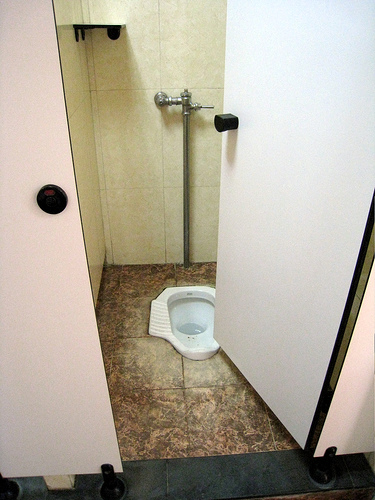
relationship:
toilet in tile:
[143, 286, 226, 356] [120, 388, 187, 457]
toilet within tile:
[143, 286, 226, 356] [120, 388, 187, 457]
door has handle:
[210, 3, 373, 456] [211, 116, 239, 132]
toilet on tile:
[143, 286, 226, 356] [120, 388, 187, 457]